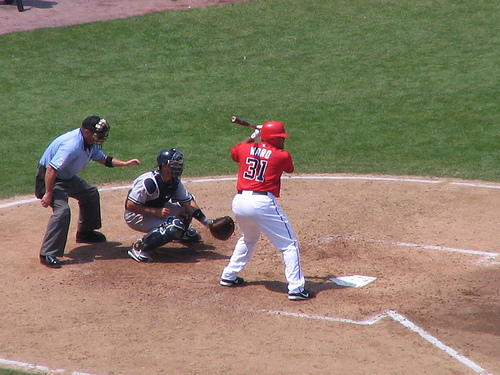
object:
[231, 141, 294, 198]
shirt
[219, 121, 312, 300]
batter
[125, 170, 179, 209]
pads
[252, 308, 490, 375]
lines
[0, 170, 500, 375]
baseball diamond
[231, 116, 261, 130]
bat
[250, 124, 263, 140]
glove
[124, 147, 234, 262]
catcher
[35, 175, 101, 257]
pants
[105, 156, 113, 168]
wrist band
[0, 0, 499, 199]
grass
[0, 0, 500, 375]
baseball field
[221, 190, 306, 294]
pants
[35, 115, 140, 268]
ref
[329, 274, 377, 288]
home plate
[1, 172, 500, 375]
dirt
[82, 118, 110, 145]
mask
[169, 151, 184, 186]
mask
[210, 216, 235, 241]
glove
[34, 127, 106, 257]
suit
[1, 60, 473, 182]
grass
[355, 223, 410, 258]
baseball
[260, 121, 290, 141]
helmet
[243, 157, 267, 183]
31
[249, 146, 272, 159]
ward